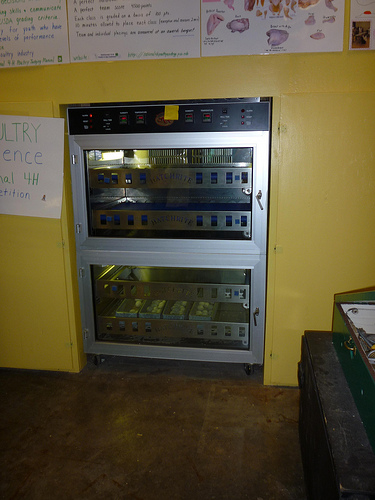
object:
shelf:
[84, 162, 252, 189]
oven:
[66, 100, 272, 376]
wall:
[282, 83, 375, 270]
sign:
[0, 115, 65, 220]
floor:
[2, 401, 220, 499]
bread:
[135, 301, 141, 307]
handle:
[255, 190, 264, 211]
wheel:
[245, 364, 255, 376]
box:
[331, 284, 373, 446]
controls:
[68, 100, 270, 137]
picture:
[266, 29, 290, 47]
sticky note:
[164, 104, 180, 120]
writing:
[73, 1, 199, 38]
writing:
[0, 0, 61, 64]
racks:
[88, 264, 250, 353]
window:
[80, 146, 253, 240]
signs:
[0, 2, 375, 72]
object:
[211, 172, 218, 184]